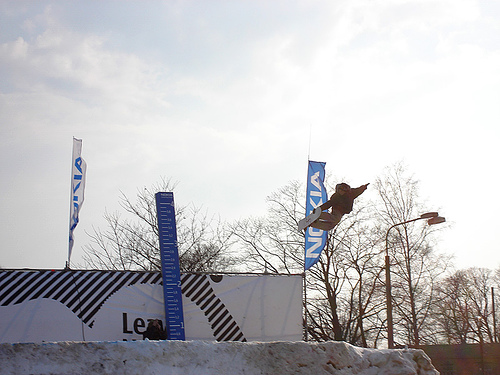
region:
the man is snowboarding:
[285, 170, 356, 233]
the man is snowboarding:
[274, 173, 366, 268]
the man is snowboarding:
[277, 175, 465, 318]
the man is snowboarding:
[296, 161, 395, 308]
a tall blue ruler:
[136, 150, 203, 355]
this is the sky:
[78, 24, 225, 106]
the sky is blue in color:
[143, 15, 215, 71]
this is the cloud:
[209, 68, 256, 116]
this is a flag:
[53, 137, 91, 253]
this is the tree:
[376, 171, 434, 283]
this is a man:
[301, 177, 368, 256]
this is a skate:
[296, 205, 326, 223]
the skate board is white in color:
[296, 215, 308, 238]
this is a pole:
[379, 236, 409, 357]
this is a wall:
[438, 337, 495, 374]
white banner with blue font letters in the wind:
[70, 134, 86, 269]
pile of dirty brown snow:
[1, 342, 441, 373]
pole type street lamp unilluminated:
[385, 212, 447, 347]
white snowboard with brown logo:
[295, 207, 320, 232]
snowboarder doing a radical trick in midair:
[296, 172, 378, 231]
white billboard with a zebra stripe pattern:
[0, 268, 305, 343]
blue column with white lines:
[154, 189, 184, 339]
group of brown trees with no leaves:
[427, 265, 497, 345]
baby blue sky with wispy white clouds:
[29, 17, 496, 142]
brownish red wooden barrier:
[430, 347, 496, 374]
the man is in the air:
[287, 165, 377, 250]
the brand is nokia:
[294, 165, 344, 263]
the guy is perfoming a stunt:
[298, 170, 373, 241]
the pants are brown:
[318, 206, 340, 236]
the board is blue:
[153, 187, 193, 343]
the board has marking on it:
[153, 189, 194, 340]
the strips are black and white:
[34, 280, 109, 299]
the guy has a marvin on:
[321, 179, 369, 217]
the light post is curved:
[370, 207, 462, 333]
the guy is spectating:
[131, 318, 187, 343]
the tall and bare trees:
[71, 159, 498, 374]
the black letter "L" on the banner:
[122, 311, 133, 333]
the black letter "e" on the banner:
[132, 316, 145, 335]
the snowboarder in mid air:
[297, 182, 371, 232]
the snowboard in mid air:
[297, 208, 321, 233]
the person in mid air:
[302, 182, 370, 234]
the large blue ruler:
[154, 191, 186, 341]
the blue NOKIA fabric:
[304, 159, 327, 266]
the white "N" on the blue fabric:
[304, 235, 322, 258]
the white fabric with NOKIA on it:
[67, 137, 87, 262]